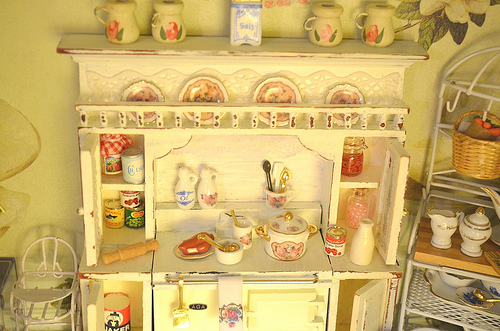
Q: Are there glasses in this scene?
A: No, there are no glasses.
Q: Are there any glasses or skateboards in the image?
A: No, there are no glasses or skateboards.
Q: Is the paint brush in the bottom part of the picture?
A: Yes, the paint brush is in the bottom of the image.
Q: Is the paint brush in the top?
A: No, the paint brush is in the bottom of the image.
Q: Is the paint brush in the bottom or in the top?
A: The paint brush is in the bottom of the image.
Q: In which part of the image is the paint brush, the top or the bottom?
A: The paint brush is in the bottom of the image.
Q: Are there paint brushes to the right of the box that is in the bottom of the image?
A: Yes, there is a paint brush to the right of the box.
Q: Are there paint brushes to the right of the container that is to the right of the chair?
A: Yes, there is a paint brush to the right of the box.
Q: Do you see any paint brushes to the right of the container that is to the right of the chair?
A: Yes, there is a paint brush to the right of the box.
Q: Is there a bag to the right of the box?
A: No, there is a paint brush to the right of the box.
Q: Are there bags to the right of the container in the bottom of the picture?
A: No, there is a paint brush to the right of the box.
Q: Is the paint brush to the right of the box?
A: Yes, the paint brush is to the right of the box.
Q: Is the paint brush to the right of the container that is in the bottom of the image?
A: Yes, the paint brush is to the right of the box.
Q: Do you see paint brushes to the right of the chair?
A: Yes, there is a paint brush to the right of the chair.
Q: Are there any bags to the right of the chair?
A: No, there is a paint brush to the right of the chair.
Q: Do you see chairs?
A: Yes, there is a chair.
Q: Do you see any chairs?
A: Yes, there is a chair.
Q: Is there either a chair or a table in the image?
A: Yes, there is a chair.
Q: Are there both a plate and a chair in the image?
A: Yes, there are both a chair and a plate.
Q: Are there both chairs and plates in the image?
A: Yes, there are both a chair and a plate.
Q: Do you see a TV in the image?
A: No, there are no televisions.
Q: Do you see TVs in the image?
A: No, there are no tvs.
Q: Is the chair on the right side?
A: No, the chair is on the left of the image.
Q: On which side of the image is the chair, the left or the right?
A: The chair is on the left of the image.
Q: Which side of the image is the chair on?
A: The chair is on the left of the image.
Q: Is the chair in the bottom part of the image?
A: Yes, the chair is in the bottom of the image.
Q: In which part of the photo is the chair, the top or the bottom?
A: The chair is in the bottom of the image.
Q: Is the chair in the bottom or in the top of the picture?
A: The chair is in the bottom of the image.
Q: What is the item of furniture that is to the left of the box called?
A: The piece of furniture is a chair.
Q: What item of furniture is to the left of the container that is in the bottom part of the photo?
A: The piece of furniture is a chair.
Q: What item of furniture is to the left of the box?
A: The piece of furniture is a chair.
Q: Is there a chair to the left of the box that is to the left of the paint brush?
A: Yes, there is a chair to the left of the box.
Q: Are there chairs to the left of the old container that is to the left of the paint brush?
A: Yes, there is a chair to the left of the box.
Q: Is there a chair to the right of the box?
A: No, the chair is to the left of the box.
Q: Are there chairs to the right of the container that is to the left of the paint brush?
A: No, the chair is to the left of the box.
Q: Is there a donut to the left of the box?
A: No, there is a chair to the left of the box.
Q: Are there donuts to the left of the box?
A: No, there is a chair to the left of the box.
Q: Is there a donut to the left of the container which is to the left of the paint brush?
A: No, there is a chair to the left of the box.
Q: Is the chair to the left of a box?
A: Yes, the chair is to the left of a box.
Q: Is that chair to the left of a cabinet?
A: No, the chair is to the left of a box.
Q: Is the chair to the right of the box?
A: No, the chair is to the left of the box.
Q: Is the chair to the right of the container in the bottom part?
A: No, the chair is to the left of the box.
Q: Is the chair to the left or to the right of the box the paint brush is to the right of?
A: The chair is to the left of the box.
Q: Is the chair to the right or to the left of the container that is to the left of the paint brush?
A: The chair is to the left of the box.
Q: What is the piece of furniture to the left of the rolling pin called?
A: The piece of furniture is a chair.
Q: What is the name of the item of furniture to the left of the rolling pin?
A: The piece of furniture is a chair.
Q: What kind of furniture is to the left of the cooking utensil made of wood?
A: The piece of furniture is a chair.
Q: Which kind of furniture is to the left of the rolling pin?
A: The piece of furniture is a chair.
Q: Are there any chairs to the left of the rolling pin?
A: Yes, there is a chair to the left of the rolling pin.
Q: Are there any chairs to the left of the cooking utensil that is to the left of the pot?
A: Yes, there is a chair to the left of the rolling pin.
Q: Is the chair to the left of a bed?
A: No, the chair is to the left of the rolling pin.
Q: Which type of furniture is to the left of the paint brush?
A: The piece of furniture is a chair.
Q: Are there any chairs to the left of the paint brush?
A: Yes, there is a chair to the left of the paint brush.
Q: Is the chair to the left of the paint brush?
A: Yes, the chair is to the left of the paint brush.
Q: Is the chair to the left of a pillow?
A: No, the chair is to the left of the paint brush.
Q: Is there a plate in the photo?
A: Yes, there is a plate.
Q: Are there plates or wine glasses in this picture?
A: Yes, there is a plate.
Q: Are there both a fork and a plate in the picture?
A: No, there is a plate but no forks.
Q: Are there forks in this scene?
A: No, there are no forks.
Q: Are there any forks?
A: No, there are no forks.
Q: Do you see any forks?
A: No, there are no forks.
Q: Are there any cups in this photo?
A: Yes, there is a cup.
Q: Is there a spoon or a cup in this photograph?
A: Yes, there is a cup.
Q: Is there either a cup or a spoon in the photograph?
A: Yes, there is a cup.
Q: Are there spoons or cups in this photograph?
A: Yes, there is a cup.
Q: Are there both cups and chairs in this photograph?
A: Yes, there are both a cup and a chair.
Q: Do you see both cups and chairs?
A: Yes, there are both a cup and a chair.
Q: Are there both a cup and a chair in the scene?
A: Yes, there are both a cup and a chair.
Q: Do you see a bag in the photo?
A: No, there are no bags.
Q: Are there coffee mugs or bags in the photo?
A: No, there are no bags or coffee mugs.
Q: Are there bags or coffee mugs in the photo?
A: No, there are no bags or coffee mugs.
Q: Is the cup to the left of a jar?
A: Yes, the cup is to the left of a jar.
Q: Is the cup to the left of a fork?
A: No, the cup is to the left of a jar.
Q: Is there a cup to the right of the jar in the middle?
A: Yes, there is a cup to the right of the jar.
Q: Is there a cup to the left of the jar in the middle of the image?
A: No, the cup is to the right of the jar.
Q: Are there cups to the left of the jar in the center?
A: No, the cup is to the right of the jar.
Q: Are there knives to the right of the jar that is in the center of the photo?
A: No, there is a cup to the right of the jar.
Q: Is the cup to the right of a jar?
A: Yes, the cup is to the right of a jar.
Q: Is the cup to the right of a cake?
A: No, the cup is to the right of a jar.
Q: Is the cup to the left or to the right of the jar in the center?
A: The cup is to the right of the jar.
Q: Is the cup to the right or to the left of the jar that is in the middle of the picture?
A: The cup is to the right of the jar.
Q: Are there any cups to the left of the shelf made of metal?
A: Yes, there is a cup to the left of the shelf.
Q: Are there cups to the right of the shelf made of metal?
A: No, the cup is to the left of the shelf.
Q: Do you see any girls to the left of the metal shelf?
A: No, there is a cup to the left of the shelf.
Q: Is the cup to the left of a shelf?
A: Yes, the cup is to the left of a shelf.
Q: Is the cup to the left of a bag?
A: No, the cup is to the left of a shelf.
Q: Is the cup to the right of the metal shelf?
A: No, the cup is to the left of the shelf.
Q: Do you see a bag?
A: No, there are no bags.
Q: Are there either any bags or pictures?
A: No, there are no bags or pictures.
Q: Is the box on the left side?
A: Yes, the box is on the left of the image.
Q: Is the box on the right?
A: No, the box is on the left of the image.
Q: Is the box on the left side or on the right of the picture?
A: The box is on the left of the image.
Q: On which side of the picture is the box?
A: The box is on the left of the image.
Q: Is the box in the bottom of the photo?
A: Yes, the box is in the bottom of the image.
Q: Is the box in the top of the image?
A: No, the box is in the bottom of the image.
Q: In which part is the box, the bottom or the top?
A: The box is in the bottom of the image.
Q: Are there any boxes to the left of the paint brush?
A: Yes, there is a box to the left of the paint brush.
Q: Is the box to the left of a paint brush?
A: Yes, the box is to the left of a paint brush.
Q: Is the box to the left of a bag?
A: No, the box is to the left of a paint brush.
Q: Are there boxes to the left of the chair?
A: No, the box is to the right of the chair.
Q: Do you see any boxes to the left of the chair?
A: No, the box is to the right of the chair.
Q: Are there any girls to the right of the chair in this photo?
A: No, there is a box to the right of the chair.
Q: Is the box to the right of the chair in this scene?
A: Yes, the box is to the right of the chair.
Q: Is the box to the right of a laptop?
A: No, the box is to the right of the chair.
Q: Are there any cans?
A: Yes, there is a can.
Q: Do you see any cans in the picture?
A: Yes, there is a can.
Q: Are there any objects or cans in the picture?
A: Yes, there is a can.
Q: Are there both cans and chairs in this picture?
A: Yes, there are both a can and a chair.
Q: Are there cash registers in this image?
A: No, there are no cash registers.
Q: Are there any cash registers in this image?
A: No, there are no cash registers.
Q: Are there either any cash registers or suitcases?
A: No, there are no cash registers or suitcases.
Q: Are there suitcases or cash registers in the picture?
A: No, there are no cash registers or suitcases.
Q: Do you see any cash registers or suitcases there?
A: No, there are no cash registers or suitcases.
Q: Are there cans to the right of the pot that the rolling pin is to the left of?
A: Yes, there is a can to the right of the pot.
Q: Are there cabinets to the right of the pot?
A: No, there is a can to the right of the pot.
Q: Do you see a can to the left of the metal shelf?
A: Yes, there is a can to the left of the shelf.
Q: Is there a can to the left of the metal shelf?
A: Yes, there is a can to the left of the shelf.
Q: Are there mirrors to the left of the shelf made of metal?
A: No, there is a can to the left of the shelf.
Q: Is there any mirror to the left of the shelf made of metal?
A: No, there is a can to the left of the shelf.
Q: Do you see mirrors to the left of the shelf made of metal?
A: No, there is a can to the left of the shelf.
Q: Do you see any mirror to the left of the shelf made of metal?
A: No, there is a can to the left of the shelf.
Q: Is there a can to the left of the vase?
A: Yes, there is a can to the left of the vase.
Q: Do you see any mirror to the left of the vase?
A: No, there is a can to the left of the vase.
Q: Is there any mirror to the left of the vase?
A: No, there is a can to the left of the vase.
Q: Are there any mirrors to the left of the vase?
A: No, there is a can to the left of the vase.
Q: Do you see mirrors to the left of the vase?
A: No, there is a can to the left of the vase.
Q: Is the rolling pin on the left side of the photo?
A: Yes, the rolling pin is on the left of the image.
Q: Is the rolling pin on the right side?
A: No, the rolling pin is on the left of the image.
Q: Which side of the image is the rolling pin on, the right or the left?
A: The rolling pin is on the left of the image.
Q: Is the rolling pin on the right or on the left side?
A: The rolling pin is on the left of the image.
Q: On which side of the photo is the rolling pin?
A: The rolling pin is on the left of the image.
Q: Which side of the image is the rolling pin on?
A: The rolling pin is on the left of the image.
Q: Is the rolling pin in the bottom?
A: Yes, the rolling pin is in the bottom of the image.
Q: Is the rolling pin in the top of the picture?
A: No, the rolling pin is in the bottom of the image.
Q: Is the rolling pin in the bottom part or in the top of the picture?
A: The rolling pin is in the bottom of the image.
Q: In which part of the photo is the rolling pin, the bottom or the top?
A: The rolling pin is in the bottom of the image.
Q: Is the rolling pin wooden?
A: Yes, the rolling pin is wooden.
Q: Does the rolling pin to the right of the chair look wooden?
A: Yes, the rolling pin is wooden.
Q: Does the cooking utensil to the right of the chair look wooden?
A: Yes, the rolling pin is wooden.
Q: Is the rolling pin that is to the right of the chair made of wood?
A: Yes, the rolling pin is made of wood.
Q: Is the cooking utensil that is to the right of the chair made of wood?
A: Yes, the rolling pin is made of wood.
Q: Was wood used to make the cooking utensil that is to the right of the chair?
A: Yes, the rolling pin is made of wood.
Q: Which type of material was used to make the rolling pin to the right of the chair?
A: The rolling pin is made of wood.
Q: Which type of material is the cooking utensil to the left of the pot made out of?
A: The rolling pin is made of wood.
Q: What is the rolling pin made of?
A: The rolling pin is made of wood.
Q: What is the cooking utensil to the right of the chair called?
A: The cooking utensil is a rolling pin.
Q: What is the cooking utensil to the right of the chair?
A: The cooking utensil is a rolling pin.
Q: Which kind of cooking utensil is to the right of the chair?
A: The cooking utensil is a rolling pin.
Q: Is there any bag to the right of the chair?
A: No, there is a rolling pin to the right of the chair.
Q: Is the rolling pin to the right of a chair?
A: Yes, the rolling pin is to the right of a chair.